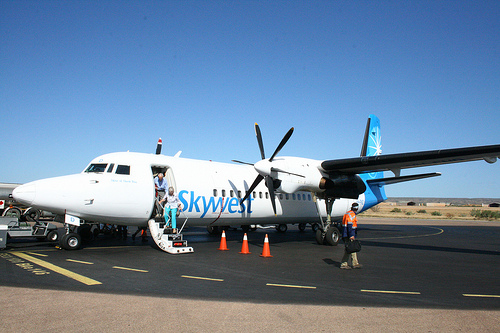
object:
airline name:
[178, 190, 255, 218]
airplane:
[11, 113, 499, 255]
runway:
[0, 217, 500, 333]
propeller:
[231, 122, 305, 217]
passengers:
[154, 172, 181, 234]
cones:
[216, 229, 231, 251]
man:
[339, 202, 365, 269]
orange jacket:
[342, 211, 358, 240]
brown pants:
[341, 240, 360, 268]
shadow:
[322, 258, 342, 268]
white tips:
[221, 232, 226, 237]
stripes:
[23, 251, 500, 297]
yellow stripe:
[8, 251, 103, 287]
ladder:
[148, 219, 195, 255]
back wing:
[366, 171, 442, 187]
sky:
[0, 7, 500, 200]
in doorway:
[150, 165, 173, 222]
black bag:
[344, 238, 362, 254]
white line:
[354, 225, 445, 240]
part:
[367, 214, 497, 227]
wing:
[320, 143, 500, 176]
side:
[148, 219, 176, 256]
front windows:
[84, 162, 108, 172]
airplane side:
[11, 151, 387, 223]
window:
[222, 189, 226, 197]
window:
[230, 190, 234, 198]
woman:
[158, 186, 181, 234]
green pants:
[163, 205, 177, 229]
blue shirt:
[154, 177, 169, 192]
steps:
[169, 240, 189, 247]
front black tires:
[59, 232, 83, 250]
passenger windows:
[213, 189, 217, 197]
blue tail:
[357, 114, 387, 214]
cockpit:
[84, 163, 131, 176]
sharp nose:
[9, 178, 94, 217]